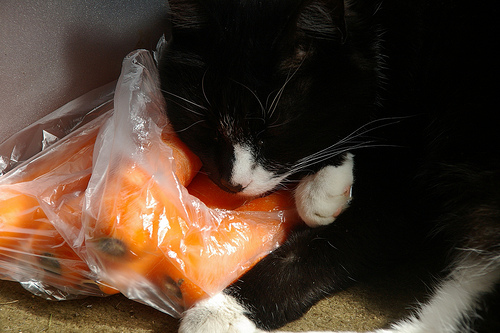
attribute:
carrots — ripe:
[2, 114, 294, 307]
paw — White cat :
[286, 152, 374, 249]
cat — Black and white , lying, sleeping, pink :
[154, 12, 498, 332]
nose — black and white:
[222, 158, 255, 194]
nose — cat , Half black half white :
[211, 156, 249, 203]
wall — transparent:
[182, 98, 282, 168]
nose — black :
[215, 146, 260, 189]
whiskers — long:
[269, 120, 371, 182]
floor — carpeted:
[313, 291, 394, 330]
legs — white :
[178, 147, 405, 332]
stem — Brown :
[97, 235, 130, 259]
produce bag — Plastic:
[2, 50, 165, 290]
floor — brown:
[0, 167, 492, 332]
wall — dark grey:
[0, 3, 148, 153]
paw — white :
[292, 149, 355, 225]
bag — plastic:
[23, 105, 170, 171]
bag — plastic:
[3, 67, 288, 300]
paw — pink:
[288, 162, 366, 224]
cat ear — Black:
[157, 2, 207, 45]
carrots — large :
[2, 88, 286, 320]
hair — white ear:
[259, 41, 344, 141]